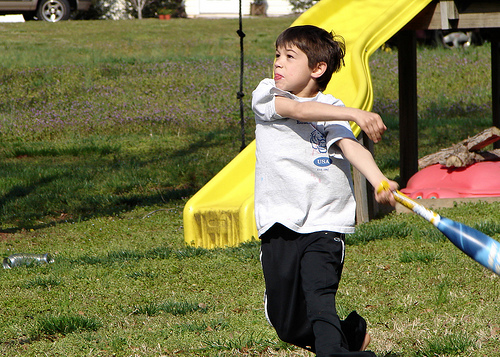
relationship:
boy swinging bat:
[253, 28, 369, 338] [375, 180, 497, 274]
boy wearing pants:
[253, 28, 369, 338] [259, 234, 349, 354]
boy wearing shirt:
[253, 28, 369, 338] [257, 98, 365, 249]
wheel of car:
[39, 3, 64, 23] [4, 1, 90, 25]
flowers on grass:
[45, 106, 178, 141] [0, 16, 498, 356]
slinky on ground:
[4, 252, 59, 275] [8, 23, 341, 337]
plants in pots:
[156, 6, 176, 17] [157, 15, 175, 21]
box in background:
[248, 2, 270, 19] [4, 4, 491, 337]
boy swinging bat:
[253, 28, 369, 338] [393, 194, 498, 275]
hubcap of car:
[47, 3, 61, 19] [4, 1, 90, 25]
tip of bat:
[375, 178, 390, 194] [375, 180, 497, 274]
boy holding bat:
[253, 28, 369, 338] [375, 180, 497, 274]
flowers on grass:
[45, 106, 178, 141] [5, 37, 226, 184]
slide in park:
[176, 6, 411, 241] [9, 23, 478, 272]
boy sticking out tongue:
[253, 28, 369, 338] [273, 71, 282, 86]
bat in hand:
[393, 194, 498, 275] [373, 183, 414, 215]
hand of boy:
[373, 183, 414, 215] [253, 28, 369, 338]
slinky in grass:
[4, 252, 58, 282] [5, 37, 226, 184]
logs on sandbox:
[410, 126, 498, 177] [384, 24, 498, 181]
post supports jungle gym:
[394, 41, 422, 168] [383, 12, 499, 167]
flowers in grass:
[45, 106, 178, 141] [5, 37, 226, 184]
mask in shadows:
[440, 32, 463, 55] [408, 29, 497, 52]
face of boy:
[262, 46, 299, 89] [253, 28, 369, 338]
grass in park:
[5, 37, 226, 184] [9, 23, 478, 272]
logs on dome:
[410, 126, 498, 177] [397, 159, 498, 198]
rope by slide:
[233, 10, 250, 148] [176, 6, 411, 241]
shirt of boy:
[257, 98, 365, 249] [253, 24, 399, 357]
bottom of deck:
[416, 5, 496, 35] [407, 4, 477, 34]